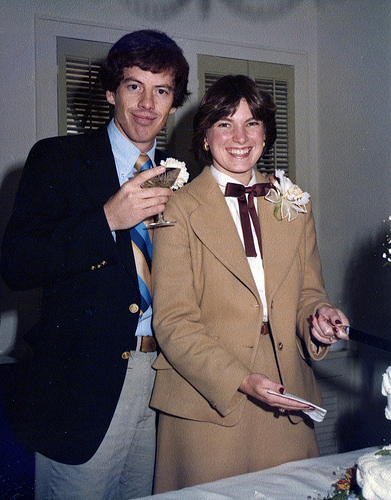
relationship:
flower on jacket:
[267, 168, 312, 220] [150, 163, 336, 426]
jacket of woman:
[150, 163, 336, 426] [146, 71, 352, 473]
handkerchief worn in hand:
[266, 386, 328, 424] [244, 371, 314, 413]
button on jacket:
[207, 399, 218, 409] [150, 163, 336, 426]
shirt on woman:
[211, 164, 269, 321] [146, 71, 352, 473]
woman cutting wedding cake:
[146, 71, 352, 473] [357, 447, 389, 495]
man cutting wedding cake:
[0, 29, 193, 500] [357, 447, 389, 495]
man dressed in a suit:
[0, 29, 193, 500] [3, 124, 180, 497]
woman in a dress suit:
[146, 71, 352, 473] [153, 152, 344, 478]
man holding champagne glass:
[0, 29, 193, 500] [139, 168, 178, 226]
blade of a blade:
[344, 322, 390, 353] [346, 326, 391, 352]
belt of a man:
[129, 332, 161, 353] [0, 29, 193, 500]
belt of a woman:
[260, 321, 270, 334] [146, 71, 352, 473]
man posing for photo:
[0, 29, 193, 500] [0, 0, 389, 499]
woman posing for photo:
[146, 71, 352, 473] [0, 0, 389, 499]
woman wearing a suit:
[146, 71, 352, 473] [163, 166, 345, 495]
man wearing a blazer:
[1, 27, 222, 499] [17, 116, 152, 473]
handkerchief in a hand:
[266, 389, 328, 424] [228, 364, 309, 430]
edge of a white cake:
[357, 456, 374, 497] [359, 365, 389, 499]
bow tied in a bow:
[225, 181, 278, 257] [218, 179, 282, 258]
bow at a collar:
[218, 179, 282, 258] [187, 166, 275, 202]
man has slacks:
[1, 27, 222, 499] [18, 334, 166, 498]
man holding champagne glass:
[0, 29, 193, 500] [133, 168, 181, 227]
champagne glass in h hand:
[133, 168, 181, 227] [100, 164, 173, 233]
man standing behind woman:
[0, 29, 193, 500] [146, 71, 352, 473]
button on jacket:
[128, 300, 140, 319] [60, 141, 115, 180]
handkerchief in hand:
[266, 389, 328, 424] [239, 373, 316, 413]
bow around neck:
[225, 181, 278, 257] [210, 161, 259, 189]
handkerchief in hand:
[266, 389, 328, 424] [244, 366, 313, 424]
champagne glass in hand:
[133, 168, 181, 227] [100, 164, 173, 233]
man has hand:
[0, 29, 193, 500] [100, 164, 173, 233]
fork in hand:
[330, 304, 370, 350] [298, 288, 352, 358]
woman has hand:
[146, 73, 352, 500] [298, 288, 352, 358]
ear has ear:
[201, 126, 208, 152] [203, 132, 209, 151]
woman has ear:
[146, 71, 352, 473] [201, 126, 208, 152]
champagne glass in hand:
[133, 168, 181, 227] [110, 165, 171, 234]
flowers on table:
[305, 462, 364, 498] [115, 440, 389, 499]